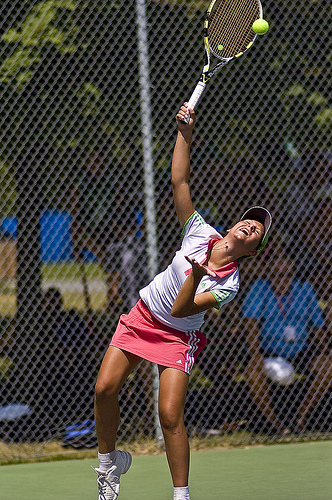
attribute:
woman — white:
[135, 182, 272, 408]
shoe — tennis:
[87, 444, 140, 497]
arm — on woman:
[150, 129, 212, 206]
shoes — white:
[89, 451, 134, 498]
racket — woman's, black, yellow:
[172, 0, 266, 124]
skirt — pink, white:
[102, 304, 212, 379]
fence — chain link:
[10, 423, 324, 449]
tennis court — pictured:
[192, 444, 330, 496]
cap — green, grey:
[243, 207, 281, 251]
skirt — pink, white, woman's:
[112, 316, 193, 373]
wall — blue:
[1, 205, 220, 268]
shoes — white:
[85, 443, 130, 479]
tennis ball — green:
[251, 18, 268, 34]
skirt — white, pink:
[109, 299, 203, 368]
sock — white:
[82, 445, 128, 480]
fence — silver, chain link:
[1, 5, 330, 451]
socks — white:
[95, 444, 120, 482]